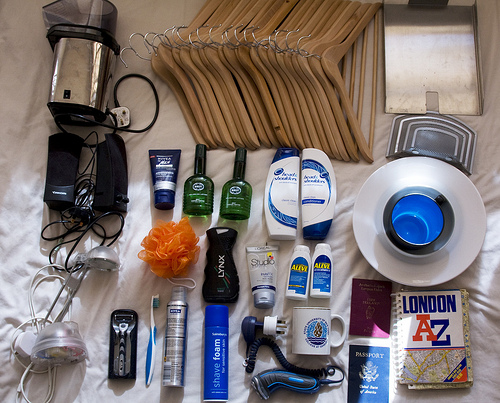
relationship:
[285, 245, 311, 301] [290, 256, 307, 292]
bottle with blue label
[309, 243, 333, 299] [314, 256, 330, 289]
pain medication with blue label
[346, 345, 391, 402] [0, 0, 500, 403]
passport on sheet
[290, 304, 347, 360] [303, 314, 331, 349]
white mug has blue design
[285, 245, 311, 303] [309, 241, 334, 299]
bottle contains bottle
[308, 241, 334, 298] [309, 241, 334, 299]
bottle contains bottle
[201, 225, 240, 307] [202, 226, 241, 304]
bottle contains shampoo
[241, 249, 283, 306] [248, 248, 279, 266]
hair gel has brand studio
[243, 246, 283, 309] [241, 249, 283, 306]
tube contains hair gel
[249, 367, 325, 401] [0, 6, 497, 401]
shaver on sheet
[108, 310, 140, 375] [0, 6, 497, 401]
razor on sheet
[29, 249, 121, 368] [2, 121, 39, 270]
lamp on sheet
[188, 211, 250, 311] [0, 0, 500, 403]
shampoo on sheet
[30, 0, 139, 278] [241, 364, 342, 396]
razor has legs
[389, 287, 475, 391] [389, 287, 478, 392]
map has map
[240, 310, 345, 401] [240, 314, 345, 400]
shaving implements used for legs